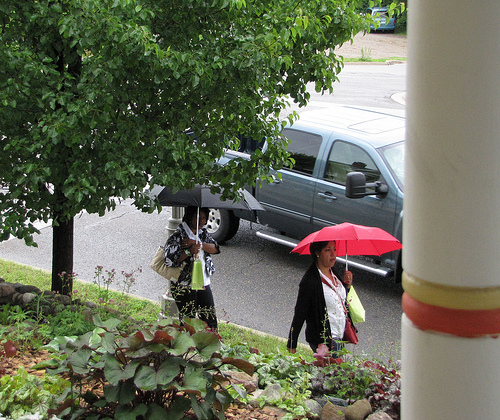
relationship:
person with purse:
[287, 240, 366, 361] [320, 275, 358, 345]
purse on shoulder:
[320, 275, 358, 345] [305, 268, 321, 301]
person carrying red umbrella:
[277, 228, 369, 371] [284, 213, 409, 265]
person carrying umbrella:
[148, 200, 219, 335] [153, 174, 262, 255]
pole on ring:
[387, 0, 499, 419] [389, 257, 499, 347]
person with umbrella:
[164, 206, 218, 335] [146, 176, 260, 215]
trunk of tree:
[45, 194, 79, 296] [7, 2, 353, 361]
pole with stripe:
[398, 0, 499, 419] [407, 274, 498, 304]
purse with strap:
[319, 273, 359, 344] [319, 274, 348, 319]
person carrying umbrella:
[287, 240, 366, 361] [279, 218, 407, 266]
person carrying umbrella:
[287, 240, 366, 361] [126, 174, 272, 222]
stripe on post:
[398, 264, 498, 346] [381, 1, 486, 417]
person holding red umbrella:
[287, 240, 366, 361] [290, 221, 403, 283]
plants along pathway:
[1, 307, 401, 419] [11, 265, 395, 385]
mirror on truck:
[341, 167, 385, 203] [170, 106, 420, 286]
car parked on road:
[182, 105, 405, 284] [0, 61, 405, 389]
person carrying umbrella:
[287, 240, 366, 361] [277, 218, 413, 257]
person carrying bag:
[287, 240, 366, 361] [346, 285, 368, 323]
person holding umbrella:
[287, 240, 366, 361] [286, 220, 402, 272]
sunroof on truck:
[351, 114, 407, 138] [165, 98, 405, 284]